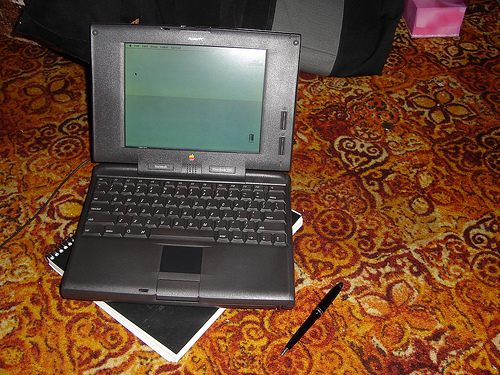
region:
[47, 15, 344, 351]
a laptop computer on a notebook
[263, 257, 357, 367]
a black pen next to the laptop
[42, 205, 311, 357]
a black and white notebook beneath the laptop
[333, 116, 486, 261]
an orange and red printed rug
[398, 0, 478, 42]
a pink box in the room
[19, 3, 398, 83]
a gray and black bag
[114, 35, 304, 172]
this is an Apple computer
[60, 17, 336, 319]
this laptop is colored dark gray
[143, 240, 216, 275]
the track roller on the laptop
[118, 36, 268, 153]
some text is on the screen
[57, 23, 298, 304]
A black laptop with the top open.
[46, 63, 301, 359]
A black notebook beneath the laptop.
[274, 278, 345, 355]
A black pen on top of a bedspread.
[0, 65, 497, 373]
Orange floral bedspread.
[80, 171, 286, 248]
The laptop keyboard.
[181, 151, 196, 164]
A red apple symbol below the laptop screen.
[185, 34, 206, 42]
Letters in white above the laptop screen.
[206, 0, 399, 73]
Black bag with a gray stripe in the middle.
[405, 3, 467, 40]
Edge of a pink tissue box.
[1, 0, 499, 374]
A bed covered with an orange floral bedspread.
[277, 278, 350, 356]
black pen on floor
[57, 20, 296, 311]
black computer on floor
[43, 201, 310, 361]
black notebook under computer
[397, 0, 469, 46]
pink box on floor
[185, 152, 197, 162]
apple symbol on computer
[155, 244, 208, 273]
black mouse pad on computer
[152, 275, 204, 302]
black button on pad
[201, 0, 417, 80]
black and grey pack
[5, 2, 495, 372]
orange tiled floor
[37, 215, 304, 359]
white paper in black notebook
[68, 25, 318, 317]
This is a laptop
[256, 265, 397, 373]
A pen on the bed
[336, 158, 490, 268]
There is a pattern on the surface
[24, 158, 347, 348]
A notebook underneath the laptop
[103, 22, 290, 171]
The laptop is on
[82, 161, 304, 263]
These are the keyboards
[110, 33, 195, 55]
The tabs on the screen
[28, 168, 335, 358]
Notebook is black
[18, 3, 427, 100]
A bag behind the laptop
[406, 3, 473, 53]
This is a pink box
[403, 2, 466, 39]
a pink box of tissue on a carpet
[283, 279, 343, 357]
a black pen on a carpet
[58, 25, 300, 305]
a silver laptop on a notebook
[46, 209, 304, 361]
a black spiral notebook on a carpet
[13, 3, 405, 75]
a black bag on a carpet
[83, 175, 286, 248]
keyboard on a laptop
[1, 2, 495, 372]
a colorful orange carpet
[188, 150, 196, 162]
a logo on a laptop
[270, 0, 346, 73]
a gray thick line on a black bag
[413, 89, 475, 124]
a flower design on a carpet